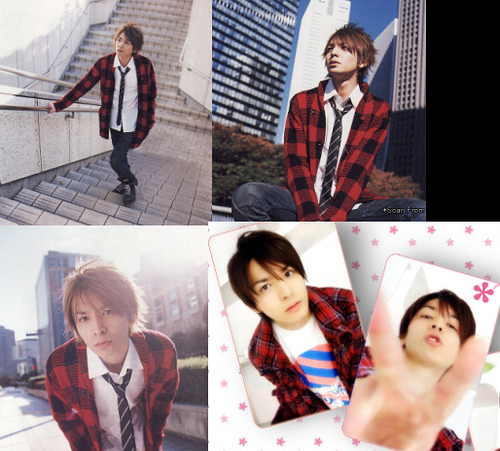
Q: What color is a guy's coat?
A: Red and black.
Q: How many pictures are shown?
A: Four.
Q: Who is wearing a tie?
A: A guy.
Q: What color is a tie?
A: Black and white.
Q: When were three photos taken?
A: Daytime.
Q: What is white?
A: The man's shirt.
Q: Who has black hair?
A: The guy.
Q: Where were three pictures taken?
A: In a city.